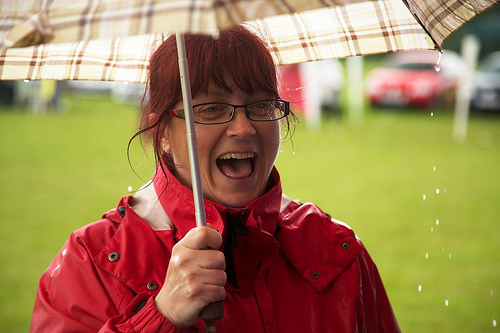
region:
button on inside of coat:
[101, 247, 126, 267]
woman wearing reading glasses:
[168, 95, 297, 126]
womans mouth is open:
[208, 145, 265, 190]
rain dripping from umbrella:
[423, 47, 450, 90]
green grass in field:
[384, 181, 407, 208]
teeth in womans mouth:
[224, 153, 259, 160]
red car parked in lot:
[367, 66, 444, 111]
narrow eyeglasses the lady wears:
[165, 92, 298, 128]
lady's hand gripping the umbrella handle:
[148, 220, 240, 310]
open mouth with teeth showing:
[207, 142, 266, 184]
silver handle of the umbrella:
[163, 32, 211, 240]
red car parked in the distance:
[364, 47, 459, 118]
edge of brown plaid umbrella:
[12, 4, 214, 53]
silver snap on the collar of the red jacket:
[106, 249, 123, 267]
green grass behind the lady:
[358, 145, 490, 229]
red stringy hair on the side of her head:
[137, 54, 176, 172]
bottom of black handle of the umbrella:
[193, 301, 230, 326]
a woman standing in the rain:
[78, 15, 404, 315]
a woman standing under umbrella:
[92, 47, 349, 279]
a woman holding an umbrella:
[112, 4, 488, 325]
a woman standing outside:
[18, 34, 428, 311]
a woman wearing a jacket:
[85, 118, 386, 325]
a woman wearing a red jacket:
[116, 90, 382, 320]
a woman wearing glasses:
[127, 51, 264, 176]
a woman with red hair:
[152, 4, 279, 189]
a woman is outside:
[62, 18, 419, 330]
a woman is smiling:
[115, 45, 307, 232]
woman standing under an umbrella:
[2, 0, 453, 331]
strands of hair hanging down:
[119, 110, 166, 186]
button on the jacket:
[103, 248, 123, 265]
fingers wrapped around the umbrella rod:
[168, 215, 246, 318]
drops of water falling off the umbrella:
[393, 47, 483, 323]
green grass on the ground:
[2, 100, 499, 329]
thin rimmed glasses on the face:
[158, 97, 299, 134]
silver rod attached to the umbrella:
[174, 30, 234, 320]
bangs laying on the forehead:
[160, 41, 270, 94]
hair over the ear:
[124, 105, 186, 197]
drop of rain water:
[432, 64, 442, 72]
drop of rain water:
[429, 109, 436, 116]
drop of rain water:
[415, 285, 422, 292]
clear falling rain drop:
[429, 60, 441, 75]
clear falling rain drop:
[427, 109, 434, 118]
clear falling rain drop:
[431, 163, 438, 173]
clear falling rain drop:
[420, 192, 426, 202]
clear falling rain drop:
[433, 188, 439, 195]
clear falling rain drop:
[433, 218, 439, 228]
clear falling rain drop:
[423, 252, 431, 259]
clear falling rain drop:
[416, 285, 427, 295]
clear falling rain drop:
[489, 318, 494, 332]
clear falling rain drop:
[431, 63, 441, 73]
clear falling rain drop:
[428, 108, 435, 118]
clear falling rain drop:
[431, 164, 437, 171]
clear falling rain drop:
[419, 191, 426, 203]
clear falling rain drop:
[433, 188, 443, 195]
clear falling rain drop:
[434, 218, 439, 227]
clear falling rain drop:
[428, 225, 437, 233]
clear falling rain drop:
[421, 252, 431, 264]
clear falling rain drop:
[416, 283, 423, 296]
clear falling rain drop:
[443, 297, 450, 306]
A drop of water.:
[491, 318, 495, 324]